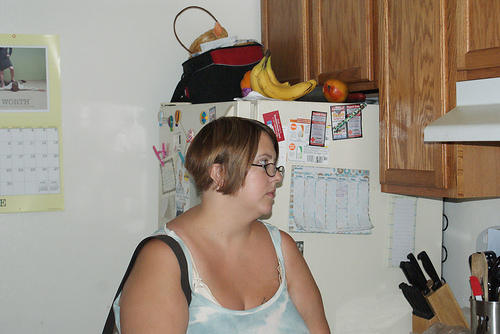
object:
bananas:
[250, 50, 317, 102]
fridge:
[160, 99, 443, 334]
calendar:
[289, 165, 374, 235]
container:
[424, 282, 470, 329]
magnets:
[168, 110, 181, 132]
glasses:
[251, 163, 284, 177]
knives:
[398, 251, 442, 321]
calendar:
[0, 34, 65, 214]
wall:
[86, 10, 152, 235]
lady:
[102, 117, 331, 334]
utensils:
[398, 251, 500, 334]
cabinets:
[260, 0, 500, 199]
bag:
[181, 41, 264, 104]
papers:
[160, 158, 176, 196]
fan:
[424, 77, 500, 142]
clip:
[153, 143, 166, 167]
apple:
[323, 79, 348, 103]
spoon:
[468, 251, 500, 302]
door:
[386, 0, 449, 190]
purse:
[101, 235, 191, 334]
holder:
[412, 279, 470, 333]